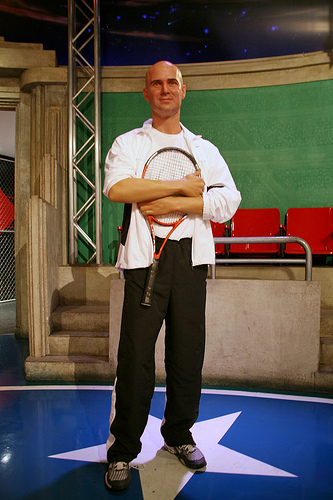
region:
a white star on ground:
[47, 404, 298, 498]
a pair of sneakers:
[102, 437, 205, 491]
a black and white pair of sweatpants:
[104, 238, 210, 460]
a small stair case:
[27, 266, 113, 382]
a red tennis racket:
[138, 144, 206, 306]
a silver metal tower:
[64, 6, 105, 263]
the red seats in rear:
[210, 203, 331, 252]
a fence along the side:
[0, 226, 15, 301]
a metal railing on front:
[203, 233, 312, 281]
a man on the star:
[102, 55, 242, 491]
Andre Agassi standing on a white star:
[105, 60, 240, 489]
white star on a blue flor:
[48, 410, 296, 498]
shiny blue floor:
[2, 390, 332, 498]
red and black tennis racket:
[140, 147, 201, 311]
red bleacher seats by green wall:
[181, 208, 332, 258]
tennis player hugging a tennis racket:
[102, 60, 239, 486]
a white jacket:
[107, 120, 241, 264]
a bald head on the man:
[144, 62, 188, 114]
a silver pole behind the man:
[68, 1, 103, 263]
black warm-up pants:
[106, 238, 205, 460]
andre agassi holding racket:
[93, 58, 249, 495]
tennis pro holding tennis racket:
[84, 54, 233, 493]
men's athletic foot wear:
[100, 430, 211, 499]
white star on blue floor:
[34, 391, 311, 499]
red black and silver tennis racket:
[130, 144, 207, 310]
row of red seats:
[105, 197, 331, 289]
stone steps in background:
[22, 264, 126, 391]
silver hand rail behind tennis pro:
[195, 229, 318, 287]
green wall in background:
[62, 72, 331, 259]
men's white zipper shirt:
[101, 118, 249, 277]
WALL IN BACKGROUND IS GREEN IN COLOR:
[78, 95, 328, 196]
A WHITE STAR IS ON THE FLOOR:
[52, 390, 287, 496]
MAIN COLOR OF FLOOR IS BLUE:
[2, 391, 296, 496]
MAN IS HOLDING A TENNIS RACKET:
[142, 144, 202, 318]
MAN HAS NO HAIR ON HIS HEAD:
[141, 56, 194, 128]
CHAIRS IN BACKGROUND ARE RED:
[214, 206, 328, 258]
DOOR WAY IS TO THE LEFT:
[0, 99, 19, 369]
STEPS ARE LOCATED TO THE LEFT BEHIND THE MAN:
[45, 267, 118, 371]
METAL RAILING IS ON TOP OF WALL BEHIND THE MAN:
[201, 242, 318, 281]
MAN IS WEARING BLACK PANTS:
[113, 224, 217, 471]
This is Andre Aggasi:
[91, 48, 228, 495]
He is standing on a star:
[45, 379, 317, 490]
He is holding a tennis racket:
[97, 141, 240, 310]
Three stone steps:
[28, 281, 116, 377]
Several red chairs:
[218, 203, 331, 252]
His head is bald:
[137, 59, 192, 118]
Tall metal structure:
[59, 6, 105, 266]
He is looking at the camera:
[132, 49, 199, 124]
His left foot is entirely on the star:
[150, 425, 217, 466]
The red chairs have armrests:
[222, 214, 328, 255]